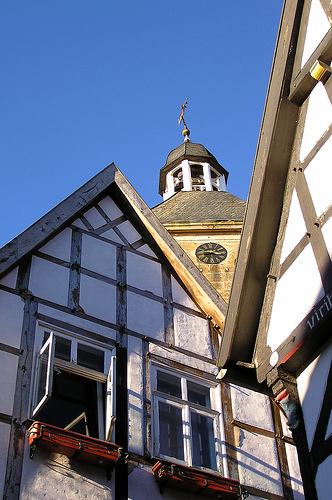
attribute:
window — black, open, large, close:
[28, 327, 139, 454]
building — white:
[32, 185, 236, 485]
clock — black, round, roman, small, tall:
[193, 227, 235, 274]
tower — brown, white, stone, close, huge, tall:
[152, 106, 243, 262]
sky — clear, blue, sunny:
[46, 32, 147, 99]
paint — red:
[280, 341, 310, 360]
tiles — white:
[229, 383, 278, 497]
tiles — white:
[125, 250, 165, 335]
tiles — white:
[81, 233, 117, 318]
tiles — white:
[28, 255, 69, 300]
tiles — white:
[278, 205, 319, 311]